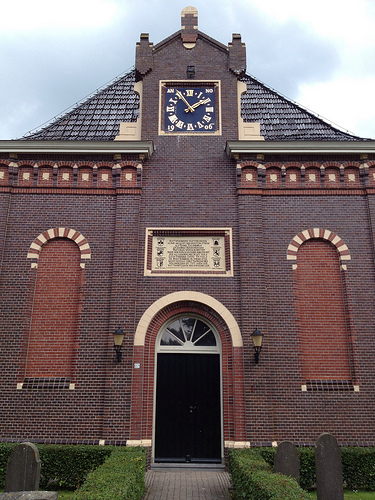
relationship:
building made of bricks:
[1, 5, 373, 498] [304, 274, 338, 336]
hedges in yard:
[2, 442, 373, 498] [1, 483, 373, 498]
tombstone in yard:
[310, 430, 346, 498] [1, 428, 369, 491]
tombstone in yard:
[2, 438, 44, 491] [1, 428, 369, 491]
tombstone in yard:
[272, 443, 297, 473] [1, 428, 369, 491]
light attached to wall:
[109, 321, 128, 366] [94, 209, 296, 440]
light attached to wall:
[246, 322, 267, 365] [94, 209, 296, 440]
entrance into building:
[130, 290, 243, 468] [1, 5, 373, 498]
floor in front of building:
[176, 91, 233, 161] [40, 129, 353, 432]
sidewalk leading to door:
[143, 464, 233, 488] [152, 346, 223, 468]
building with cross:
[1, 5, 373, 498] [179, 11, 198, 30]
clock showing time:
[163, 80, 222, 141] [175, 86, 211, 116]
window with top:
[25, 227, 93, 390] [25, 225, 89, 266]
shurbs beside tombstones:
[230, 447, 307, 497] [310, 428, 348, 498]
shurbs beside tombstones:
[230, 447, 307, 497] [271, 439, 301, 482]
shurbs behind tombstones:
[50, 440, 159, 498] [8, 439, 45, 493]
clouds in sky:
[314, 19, 364, 90] [54, 45, 90, 89]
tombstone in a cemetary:
[310, 430, 346, 498] [1, 422, 374, 499]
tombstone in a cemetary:
[272, 440, 302, 488] [1, 422, 374, 499]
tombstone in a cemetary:
[2, 438, 44, 491] [1, 422, 374, 499]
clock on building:
[166, 80, 226, 141] [1, 5, 373, 498]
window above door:
[154, 319, 223, 351] [150, 348, 229, 467]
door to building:
[150, 348, 229, 467] [1, 5, 373, 498]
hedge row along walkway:
[9, 432, 363, 486] [141, 454, 240, 496]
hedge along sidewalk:
[2, 440, 146, 497] [143, 464, 233, 500]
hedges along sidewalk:
[221, 442, 372, 499] [143, 464, 233, 500]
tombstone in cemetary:
[2, 438, 44, 491] [0, 486, 77, 497]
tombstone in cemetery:
[272, 440, 302, 488] [4, 464, 363, 489]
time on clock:
[174, 88, 210, 115] [162, 81, 217, 134]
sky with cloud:
[1, 1, 373, 136] [217, 1, 372, 137]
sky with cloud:
[1, 1, 373, 136] [0, 1, 130, 43]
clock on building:
[163, 80, 222, 141] [1, 5, 373, 498]